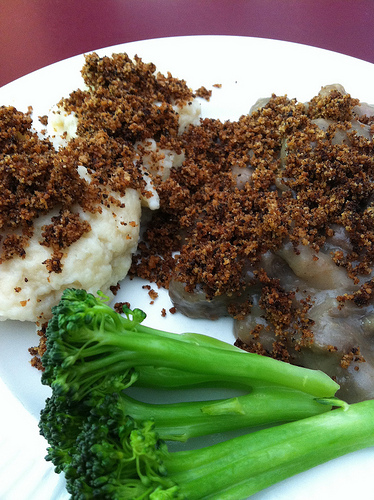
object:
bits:
[326, 343, 338, 355]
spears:
[310, 394, 353, 408]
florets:
[130, 309, 145, 329]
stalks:
[123, 333, 340, 398]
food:
[0, 164, 143, 324]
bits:
[271, 303, 285, 319]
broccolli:
[59, 387, 373, 498]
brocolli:
[38, 285, 342, 474]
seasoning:
[349, 345, 361, 359]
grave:
[328, 305, 347, 323]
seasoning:
[330, 246, 345, 269]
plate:
[0, 33, 374, 498]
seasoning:
[335, 295, 347, 313]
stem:
[119, 387, 332, 442]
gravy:
[168, 224, 374, 405]